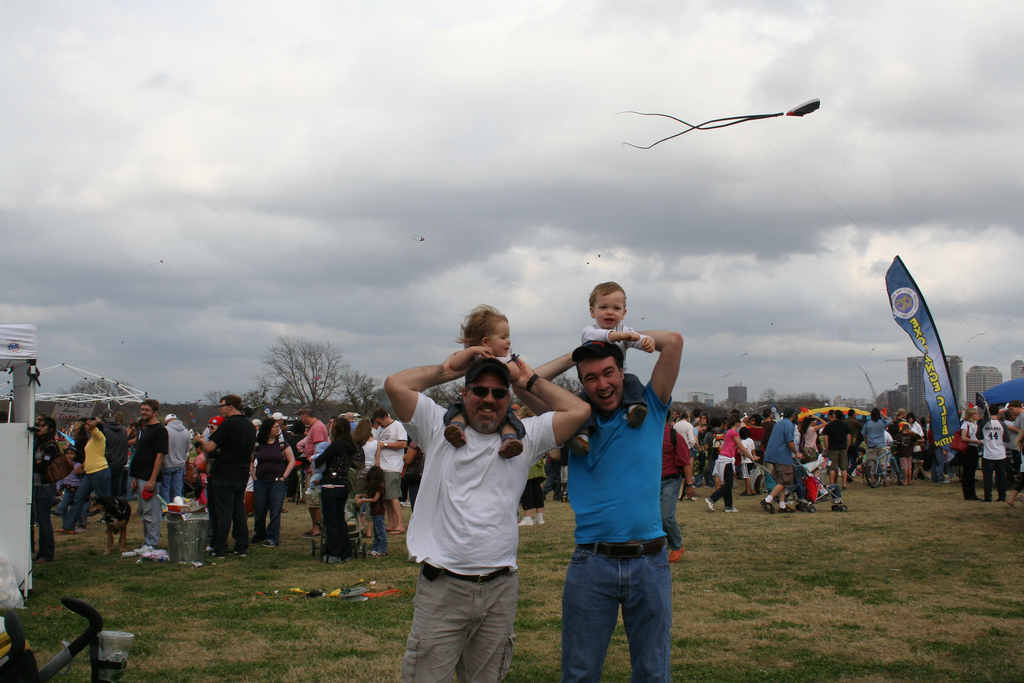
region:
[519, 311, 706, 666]
a person is standing up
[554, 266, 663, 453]
a person is sitting down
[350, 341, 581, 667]
a person is standing up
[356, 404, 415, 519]
a person is standing up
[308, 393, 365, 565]
a person is standing up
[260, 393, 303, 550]
a person is standing up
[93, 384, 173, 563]
a person is standing up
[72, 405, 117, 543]
a person is standing up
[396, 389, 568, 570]
A white shirt on a man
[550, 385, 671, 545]
A blue shirt on a man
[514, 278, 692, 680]
A man standing in the grass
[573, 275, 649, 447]
A child on a man's shoulders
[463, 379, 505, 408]
Sunglasses on a man's face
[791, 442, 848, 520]
A baby stroller in the grass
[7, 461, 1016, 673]
Grass in a field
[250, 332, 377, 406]
A tree behind a field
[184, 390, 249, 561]
people hanging out at a festival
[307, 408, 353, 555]
people hanging out at a festival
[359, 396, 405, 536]
people hanging out at a festival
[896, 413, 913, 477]
people hanging out at a festival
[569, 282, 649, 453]
baby wearing a white shirt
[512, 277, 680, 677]
man carrying a small baby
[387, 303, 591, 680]
man carrying a small baby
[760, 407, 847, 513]
man pushing a baby stroller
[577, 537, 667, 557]
man's brown leather belt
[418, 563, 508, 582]
man's brown leather belt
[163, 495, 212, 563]
overflowing metal trash can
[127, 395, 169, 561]
man wearing a black shirt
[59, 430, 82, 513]
the person is standing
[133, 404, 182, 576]
the person is standing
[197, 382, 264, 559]
the person is standing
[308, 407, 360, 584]
the person is standing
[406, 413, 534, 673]
the person is standing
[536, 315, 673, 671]
the person is standing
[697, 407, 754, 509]
the person is standing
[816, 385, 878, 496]
the person is standing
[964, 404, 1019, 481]
the person is standing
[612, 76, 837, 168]
kite in the air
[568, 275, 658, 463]
toddler looking at the camera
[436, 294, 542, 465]
toddler looking at another toddler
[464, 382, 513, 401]
sunglasses on a man's face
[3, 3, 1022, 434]
cloudy looking sky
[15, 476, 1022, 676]
yellow and green grass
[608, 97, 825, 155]
black kite on sky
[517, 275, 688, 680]
man carrying a baby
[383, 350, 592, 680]
man wearing white shirt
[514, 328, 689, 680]
man wearing blue jeans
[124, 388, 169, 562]
man standing on the grass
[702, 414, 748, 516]
woman wearing pink shirt and black pants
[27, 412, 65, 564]
young woman carrying a bag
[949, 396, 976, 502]
woman carrying a red bag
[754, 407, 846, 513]
man pushing a baby carriage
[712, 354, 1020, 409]
buildings on the distance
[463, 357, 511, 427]
person has a head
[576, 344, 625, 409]
person has a head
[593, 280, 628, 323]
person has a head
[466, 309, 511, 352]
person has a head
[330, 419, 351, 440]
person has a head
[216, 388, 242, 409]
person has a head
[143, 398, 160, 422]
person has a head